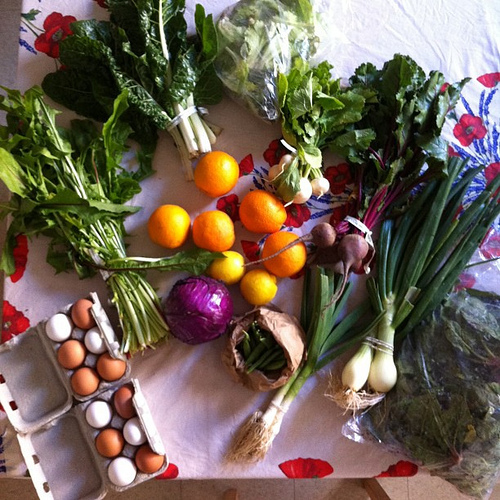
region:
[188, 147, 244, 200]
an orange with the rind on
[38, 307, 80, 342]
a white colored egg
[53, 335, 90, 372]
a brown colored egg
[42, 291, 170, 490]
a dozen brown and white eggs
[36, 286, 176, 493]
a half dozen of white eggs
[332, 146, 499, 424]
a bundle of chives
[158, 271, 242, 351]
a head of purple cabbage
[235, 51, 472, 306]
a bundle of raddishes and leafy greens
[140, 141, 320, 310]
four oranges and two lemons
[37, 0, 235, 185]
a bundle of leafy greens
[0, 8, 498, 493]
Vegetables over a table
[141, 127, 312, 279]
Five oranges in the middle of vegetables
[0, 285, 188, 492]
Eggs on a open box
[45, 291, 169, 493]
Eggs are brown and white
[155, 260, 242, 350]
Big purple onion next to limes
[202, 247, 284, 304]
Two lemons between oranges and purple onion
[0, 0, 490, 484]
Table is cover with white tablecloth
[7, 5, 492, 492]
Tablecloth has red flower designs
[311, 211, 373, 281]
Some radish next to oranges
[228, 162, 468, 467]
Two bunches of green onions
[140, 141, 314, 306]
seven oranges on a table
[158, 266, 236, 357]
a purple onion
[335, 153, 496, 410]
stalks of green onion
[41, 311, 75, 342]
a white egg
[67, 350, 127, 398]
two brown eggs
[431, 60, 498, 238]
pink flower table cloth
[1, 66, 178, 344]
green onion stalks that have been cut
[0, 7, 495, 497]
fruits, vegetables and eggs on a table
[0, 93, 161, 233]
green leaves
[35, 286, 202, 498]
dozen eggs in carton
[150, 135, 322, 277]
five oranges on table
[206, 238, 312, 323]
two lemons on table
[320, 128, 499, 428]
spring onions on table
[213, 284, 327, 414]
peas in a pod in a brown bag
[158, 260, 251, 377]
one red cabbage on table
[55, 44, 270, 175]
bunch of spinach on table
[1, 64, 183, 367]
bunch of kale on table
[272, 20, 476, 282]
bunch of beetroot on the table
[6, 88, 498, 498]
white table cloth with red flowers on it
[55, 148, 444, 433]
Food is shown here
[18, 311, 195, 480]
These are eggs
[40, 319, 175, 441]
The eggs are white and brown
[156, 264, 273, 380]
This onion is red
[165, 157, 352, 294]
These are fruits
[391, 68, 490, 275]
These vegetables are green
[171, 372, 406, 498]
The tablecloth is white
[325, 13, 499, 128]
There is light shining on the table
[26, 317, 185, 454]
The eggs are in a carton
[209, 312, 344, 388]
Edamame are in a bag